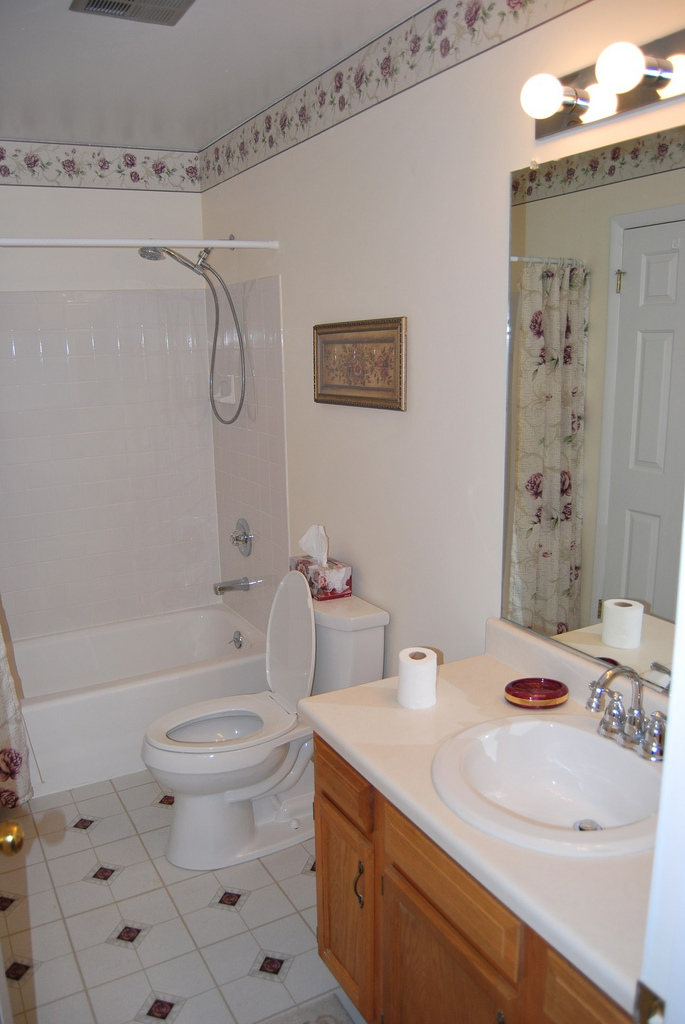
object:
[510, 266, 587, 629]
shower curtain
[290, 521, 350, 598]
tissue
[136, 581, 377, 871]
toilet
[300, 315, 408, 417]
frame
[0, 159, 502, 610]
wall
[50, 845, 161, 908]
tile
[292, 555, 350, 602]
floral design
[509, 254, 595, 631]
curtain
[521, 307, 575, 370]
floral design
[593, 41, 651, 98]
light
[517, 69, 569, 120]
light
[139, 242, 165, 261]
nozzle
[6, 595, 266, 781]
bathtub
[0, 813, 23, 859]
knob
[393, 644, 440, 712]
paper roll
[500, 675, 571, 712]
soap dish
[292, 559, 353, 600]
flowers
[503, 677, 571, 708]
bowl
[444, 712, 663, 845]
sink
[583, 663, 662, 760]
faucet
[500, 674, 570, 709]
dish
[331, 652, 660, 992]
counter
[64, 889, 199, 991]
tile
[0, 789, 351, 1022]
floor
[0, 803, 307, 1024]
floor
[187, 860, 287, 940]
tile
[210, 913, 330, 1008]
tile